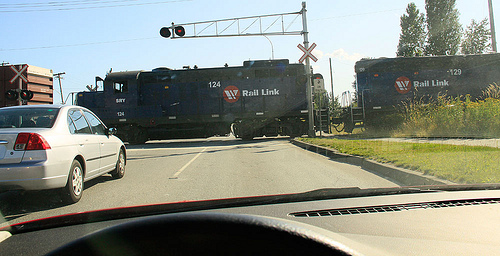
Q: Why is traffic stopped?
A: A train is crossing.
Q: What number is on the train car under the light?
A: 124.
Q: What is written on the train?
A: Rail link.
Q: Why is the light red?
A: To make cars stop.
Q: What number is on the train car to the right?
A: 129.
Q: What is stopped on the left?
A: A white car.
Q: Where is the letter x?
A: On the pole.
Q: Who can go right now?
A: The train.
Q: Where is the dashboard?
A: Inside the car.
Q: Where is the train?
A: Tracks.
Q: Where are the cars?
A: Road.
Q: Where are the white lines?
A: Road.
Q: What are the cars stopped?
A: Train crossing the road.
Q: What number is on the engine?
A: 124.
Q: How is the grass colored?
A: Green.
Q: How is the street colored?
A: Black.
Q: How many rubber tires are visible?
A: 2.